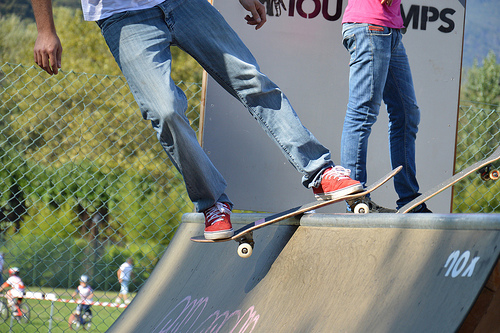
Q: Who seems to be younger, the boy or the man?
A: The boy is younger than the man.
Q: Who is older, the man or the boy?
A: The man is older than the boy.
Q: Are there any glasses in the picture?
A: No, there are no glasses.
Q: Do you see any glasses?
A: No, there are no glasses.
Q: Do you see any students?
A: No, there are no students.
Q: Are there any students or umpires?
A: No, there are no students or umpires.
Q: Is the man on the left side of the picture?
A: Yes, the man is on the left of the image.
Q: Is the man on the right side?
A: No, the man is on the left of the image.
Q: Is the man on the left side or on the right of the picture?
A: The man is on the left of the image.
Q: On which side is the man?
A: The man is on the left of the image.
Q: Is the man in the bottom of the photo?
A: Yes, the man is in the bottom of the image.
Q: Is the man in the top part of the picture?
A: No, the man is in the bottom of the image.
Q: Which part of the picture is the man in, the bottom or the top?
A: The man is in the bottom of the image.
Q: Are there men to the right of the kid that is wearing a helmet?
A: Yes, there is a man to the right of the child.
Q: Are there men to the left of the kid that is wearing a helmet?
A: No, the man is to the right of the child.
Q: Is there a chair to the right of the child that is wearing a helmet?
A: No, there is a man to the right of the child.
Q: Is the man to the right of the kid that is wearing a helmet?
A: Yes, the man is to the right of the kid.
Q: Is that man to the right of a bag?
A: No, the man is to the right of the kid.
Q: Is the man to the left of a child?
A: No, the man is to the right of a child.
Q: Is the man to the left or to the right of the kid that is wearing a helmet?
A: The man is to the right of the child.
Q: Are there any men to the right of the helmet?
A: Yes, there is a man to the right of the helmet.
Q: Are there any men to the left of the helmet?
A: No, the man is to the right of the helmet.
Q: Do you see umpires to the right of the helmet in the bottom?
A: No, there is a man to the right of the helmet.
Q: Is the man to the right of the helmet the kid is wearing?
A: Yes, the man is to the right of the helmet.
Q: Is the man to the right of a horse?
A: No, the man is to the right of the helmet.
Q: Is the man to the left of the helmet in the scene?
A: No, the man is to the right of the helmet.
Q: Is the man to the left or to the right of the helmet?
A: The man is to the right of the helmet.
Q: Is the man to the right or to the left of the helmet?
A: The man is to the right of the helmet.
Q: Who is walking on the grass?
A: The man is walking on the grass.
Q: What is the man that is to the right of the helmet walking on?
A: The man is walking on the grass.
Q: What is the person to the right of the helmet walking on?
A: The man is walking on the grass.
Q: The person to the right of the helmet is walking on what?
A: The man is walking on the grass.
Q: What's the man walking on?
A: The man is walking on the grass.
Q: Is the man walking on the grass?
A: Yes, the man is walking on the grass.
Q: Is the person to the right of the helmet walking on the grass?
A: Yes, the man is walking on the grass.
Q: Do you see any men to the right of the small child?
A: Yes, there is a man to the right of the kid.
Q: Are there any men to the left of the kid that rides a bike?
A: No, the man is to the right of the child.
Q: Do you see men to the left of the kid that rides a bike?
A: No, the man is to the right of the child.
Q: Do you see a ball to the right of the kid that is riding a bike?
A: No, there is a man to the right of the kid.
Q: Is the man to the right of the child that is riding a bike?
A: Yes, the man is to the right of the kid.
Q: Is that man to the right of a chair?
A: No, the man is to the right of the kid.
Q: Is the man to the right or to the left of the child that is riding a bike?
A: The man is to the right of the kid.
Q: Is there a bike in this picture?
A: Yes, there is a bike.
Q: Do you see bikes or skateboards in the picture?
A: Yes, there is a bike.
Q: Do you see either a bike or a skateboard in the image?
A: Yes, there is a bike.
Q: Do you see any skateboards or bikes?
A: Yes, there is a bike.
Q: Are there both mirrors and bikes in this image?
A: No, there is a bike but no mirrors.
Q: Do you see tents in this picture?
A: No, there are no tents.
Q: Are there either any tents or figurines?
A: No, there are no tents or figurines.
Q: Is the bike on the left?
A: Yes, the bike is on the left of the image.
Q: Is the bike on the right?
A: No, the bike is on the left of the image.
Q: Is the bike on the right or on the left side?
A: The bike is on the left of the image.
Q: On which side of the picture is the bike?
A: The bike is on the left of the image.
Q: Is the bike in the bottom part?
A: Yes, the bike is in the bottom of the image.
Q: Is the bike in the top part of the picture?
A: No, the bike is in the bottom of the image.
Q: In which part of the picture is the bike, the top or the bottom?
A: The bike is in the bottom of the image.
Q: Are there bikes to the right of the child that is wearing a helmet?
A: Yes, there is a bike to the right of the kid.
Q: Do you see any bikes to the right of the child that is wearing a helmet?
A: Yes, there is a bike to the right of the kid.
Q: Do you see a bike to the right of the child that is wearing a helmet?
A: Yes, there is a bike to the right of the kid.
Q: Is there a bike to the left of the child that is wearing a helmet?
A: No, the bike is to the right of the kid.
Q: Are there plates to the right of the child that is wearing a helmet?
A: No, there is a bike to the right of the kid.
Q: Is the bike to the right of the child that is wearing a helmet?
A: Yes, the bike is to the right of the child.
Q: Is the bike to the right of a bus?
A: No, the bike is to the right of the child.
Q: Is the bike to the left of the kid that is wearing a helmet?
A: No, the bike is to the right of the kid.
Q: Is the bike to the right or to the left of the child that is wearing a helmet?
A: The bike is to the right of the kid.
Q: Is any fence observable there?
A: Yes, there is a fence.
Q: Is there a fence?
A: Yes, there is a fence.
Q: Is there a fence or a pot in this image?
A: Yes, there is a fence.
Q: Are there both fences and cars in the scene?
A: No, there is a fence but no cars.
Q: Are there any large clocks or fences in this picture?
A: Yes, there is a large fence.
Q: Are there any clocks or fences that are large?
A: Yes, the fence is large.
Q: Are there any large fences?
A: Yes, there is a large fence.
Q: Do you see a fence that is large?
A: Yes, there is a fence that is large.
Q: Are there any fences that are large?
A: Yes, there is a fence that is large.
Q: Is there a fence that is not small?
A: Yes, there is a large fence.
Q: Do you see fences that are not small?
A: Yes, there is a large fence.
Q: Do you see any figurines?
A: No, there are no figurines.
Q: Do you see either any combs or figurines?
A: No, there are no figurines or combs.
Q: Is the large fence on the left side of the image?
A: Yes, the fence is on the left of the image.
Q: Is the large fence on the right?
A: No, the fence is on the left of the image.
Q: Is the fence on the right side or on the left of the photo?
A: The fence is on the left of the image.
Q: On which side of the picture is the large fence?
A: The fence is on the left of the image.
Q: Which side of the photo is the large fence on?
A: The fence is on the left of the image.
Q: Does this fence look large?
A: Yes, the fence is large.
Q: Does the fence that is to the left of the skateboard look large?
A: Yes, the fence is large.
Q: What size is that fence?
A: The fence is large.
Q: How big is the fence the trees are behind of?
A: The fence is large.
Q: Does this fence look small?
A: No, the fence is large.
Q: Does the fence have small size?
A: No, the fence is large.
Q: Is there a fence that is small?
A: No, there is a fence but it is large.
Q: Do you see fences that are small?
A: No, there is a fence but it is large.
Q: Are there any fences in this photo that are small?
A: No, there is a fence but it is large.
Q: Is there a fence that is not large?
A: No, there is a fence but it is large.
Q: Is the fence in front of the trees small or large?
A: The fence is large.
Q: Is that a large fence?
A: Yes, that is a large fence.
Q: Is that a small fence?
A: No, that is a large fence.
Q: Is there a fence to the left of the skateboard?
A: Yes, there is a fence to the left of the skateboard.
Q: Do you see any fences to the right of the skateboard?
A: No, the fence is to the left of the skateboard.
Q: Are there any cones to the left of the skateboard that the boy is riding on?
A: No, there is a fence to the left of the skateboard.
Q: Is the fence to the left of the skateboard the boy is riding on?
A: Yes, the fence is to the left of the skateboard.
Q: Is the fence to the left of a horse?
A: No, the fence is to the left of the skateboard.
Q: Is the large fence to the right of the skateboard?
A: No, the fence is to the left of the skateboard.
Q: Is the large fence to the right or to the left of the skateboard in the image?
A: The fence is to the left of the skateboard.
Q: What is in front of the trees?
A: The fence is in front of the trees.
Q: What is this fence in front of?
A: The fence is in front of the trees.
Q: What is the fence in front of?
A: The fence is in front of the trees.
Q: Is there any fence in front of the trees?
A: Yes, there is a fence in front of the trees.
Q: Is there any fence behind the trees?
A: No, the fence is in front of the trees.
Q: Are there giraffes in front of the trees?
A: No, there is a fence in front of the trees.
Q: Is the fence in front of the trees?
A: Yes, the fence is in front of the trees.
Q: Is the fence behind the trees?
A: No, the fence is in front of the trees.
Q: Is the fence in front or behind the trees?
A: The fence is in front of the trees.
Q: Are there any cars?
A: No, there are no cars.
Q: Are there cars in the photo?
A: No, there are no cars.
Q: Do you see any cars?
A: No, there are no cars.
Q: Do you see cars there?
A: No, there are no cars.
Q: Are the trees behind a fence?
A: Yes, the trees are behind a fence.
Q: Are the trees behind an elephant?
A: No, the trees are behind a fence.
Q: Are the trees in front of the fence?
A: No, the trees are behind the fence.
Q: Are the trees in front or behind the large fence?
A: The trees are behind the fence.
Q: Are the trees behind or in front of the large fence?
A: The trees are behind the fence.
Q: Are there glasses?
A: No, there are no glasses.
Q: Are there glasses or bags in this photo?
A: No, there are no glasses or bags.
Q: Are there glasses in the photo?
A: No, there are no glasses.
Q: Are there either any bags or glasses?
A: No, there are no glasses or bags.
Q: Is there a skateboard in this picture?
A: Yes, there is a skateboard.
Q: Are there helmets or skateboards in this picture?
A: Yes, there is a skateboard.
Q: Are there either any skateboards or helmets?
A: Yes, there is a skateboard.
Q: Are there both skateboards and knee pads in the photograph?
A: No, there is a skateboard but no knee pads.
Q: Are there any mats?
A: No, there are no mats.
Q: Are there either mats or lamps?
A: No, there are no mats or lamps.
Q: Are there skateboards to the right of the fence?
A: Yes, there is a skateboard to the right of the fence.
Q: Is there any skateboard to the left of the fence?
A: No, the skateboard is to the right of the fence.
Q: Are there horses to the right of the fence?
A: No, there is a skateboard to the right of the fence.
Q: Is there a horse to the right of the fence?
A: No, there is a skateboard to the right of the fence.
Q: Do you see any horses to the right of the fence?
A: No, there is a skateboard to the right of the fence.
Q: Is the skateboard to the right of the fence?
A: Yes, the skateboard is to the right of the fence.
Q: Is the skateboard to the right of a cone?
A: No, the skateboard is to the right of the fence.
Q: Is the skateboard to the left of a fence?
A: No, the skateboard is to the right of a fence.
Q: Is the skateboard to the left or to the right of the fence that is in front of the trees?
A: The skateboard is to the right of the fence.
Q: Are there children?
A: Yes, there is a child.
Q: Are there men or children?
A: Yes, there is a child.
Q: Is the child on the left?
A: Yes, the child is on the left of the image.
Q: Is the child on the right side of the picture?
A: No, the child is on the left of the image.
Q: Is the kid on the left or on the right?
A: The kid is on the left of the image.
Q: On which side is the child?
A: The child is on the left of the image.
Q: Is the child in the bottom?
A: Yes, the child is in the bottom of the image.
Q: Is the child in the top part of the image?
A: No, the child is in the bottom of the image.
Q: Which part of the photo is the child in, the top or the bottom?
A: The child is in the bottom of the image.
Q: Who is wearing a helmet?
A: The child is wearing a helmet.